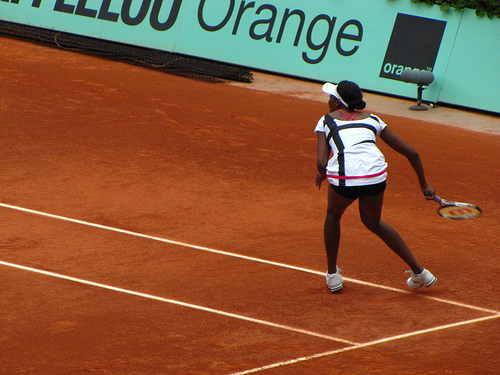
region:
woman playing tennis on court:
[313, 68, 488, 323]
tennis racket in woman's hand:
[429, 180, 483, 237]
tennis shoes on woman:
[314, 264, 438, 297]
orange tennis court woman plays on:
[6, 95, 288, 372]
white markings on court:
[21, 198, 101, 233]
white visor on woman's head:
[314, 77, 344, 96]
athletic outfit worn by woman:
[312, 107, 389, 194]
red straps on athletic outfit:
[340, 105, 358, 120]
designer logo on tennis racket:
[449, 205, 474, 217]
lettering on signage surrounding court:
[196, 3, 370, 67]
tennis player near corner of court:
[275, 40, 495, 347]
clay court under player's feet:
[67, 211, 494, 351]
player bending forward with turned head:
[305, 65, 442, 295]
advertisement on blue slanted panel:
[20, 0, 490, 100]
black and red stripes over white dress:
[301, 110, 387, 185]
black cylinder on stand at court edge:
[397, 60, 432, 110]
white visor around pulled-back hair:
[315, 70, 365, 110]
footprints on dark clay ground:
[20, 46, 300, 166]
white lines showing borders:
[1, 195, 493, 367]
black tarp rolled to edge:
[1, 15, 256, 88]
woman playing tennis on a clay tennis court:
[7, 8, 492, 358]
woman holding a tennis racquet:
[294, 64, 495, 301]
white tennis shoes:
[306, 247, 444, 292]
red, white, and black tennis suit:
[308, 74, 392, 204]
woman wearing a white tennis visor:
[314, 61, 383, 123]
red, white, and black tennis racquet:
[407, 167, 487, 238]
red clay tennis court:
[30, 108, 251, 347]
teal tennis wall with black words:
[124, 4, 454, 92]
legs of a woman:
[311, 175, 437, 282]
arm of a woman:
[309, 115, 342, 185]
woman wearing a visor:
[285, 50, 495, 320]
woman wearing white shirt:
[252, 80, 469, 320]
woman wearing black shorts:
[303, 80, 474, 310]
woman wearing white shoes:
[310, 77, 476, 313]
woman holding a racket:
[295, 75, 471, 325]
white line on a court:
[266, 353, 321, 373]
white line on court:
[395, 311, 492, 342]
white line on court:
[177, 297, 298, 333]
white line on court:
[32, 205, 125, 240]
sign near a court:
[257, 19, 366, 69]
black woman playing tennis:
[312, 75, 483, 295]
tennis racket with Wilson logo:
[428, 183, 485, 232]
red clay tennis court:
[4, 25, 499, 372]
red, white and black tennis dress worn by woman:
[313, 106, 395, 186]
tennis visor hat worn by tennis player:
[323, 77, 353, 110]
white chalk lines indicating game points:
[4, 185, 496, 365]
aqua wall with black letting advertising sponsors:
[6, 0, 498, 125]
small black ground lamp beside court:
[402, 68, 437, 112]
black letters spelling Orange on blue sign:
[183, 0, 390, 67]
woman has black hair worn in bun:
[339, 80, 366, 109]